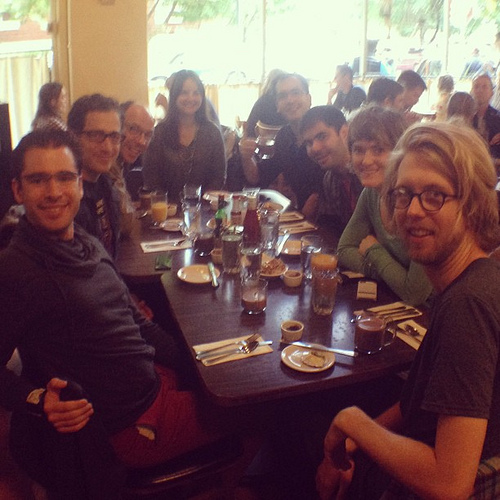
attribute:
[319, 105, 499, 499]
man — older, blond, young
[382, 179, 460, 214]
glasses — black, black rimmed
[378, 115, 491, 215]
hair — long, blonde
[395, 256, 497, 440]
shirt — blue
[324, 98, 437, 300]
woman — young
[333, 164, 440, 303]
shirt — green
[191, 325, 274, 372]
napkin — white, rectangle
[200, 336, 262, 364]
spoon — silver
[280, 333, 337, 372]
plate — round, small, white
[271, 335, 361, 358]
knife — silver, sitting, butter knife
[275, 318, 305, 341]
cup — small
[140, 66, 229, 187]
woman — smiling, brunette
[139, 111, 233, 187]
shirt — dark, gray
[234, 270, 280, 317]
mug — holding, glass, clear, sitting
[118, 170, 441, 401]
table — wood, brown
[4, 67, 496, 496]
people — smiling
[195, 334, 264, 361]
silverware — sitting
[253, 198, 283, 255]
glass — tall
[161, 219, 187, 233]
bowl — round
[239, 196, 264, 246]
bottle — glass